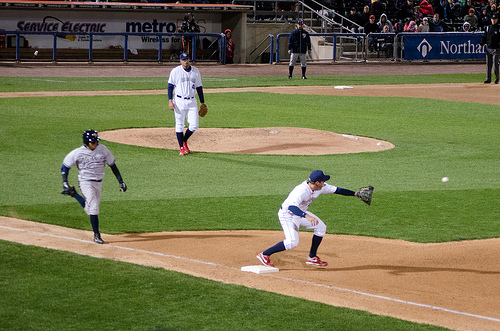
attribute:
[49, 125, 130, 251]
player — ball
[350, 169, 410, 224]
glove — leather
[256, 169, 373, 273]
player — ball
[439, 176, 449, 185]
ball — game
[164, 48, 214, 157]
player — ball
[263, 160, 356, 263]
player — ball